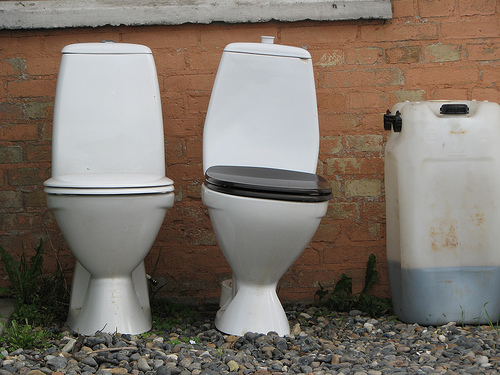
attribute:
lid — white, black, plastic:
[35, 161, 158, 201]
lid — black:
[193, 145, 335, 211]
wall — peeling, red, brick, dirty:
[319, 38, 454, 158]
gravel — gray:
[167, 331, 229, 371]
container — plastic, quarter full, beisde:
[368, 78, 484, 247]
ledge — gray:
[132, 7, 220, 29]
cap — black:
[425, 96, 473, 114]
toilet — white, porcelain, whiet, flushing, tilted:
[190, 28, 317, 214]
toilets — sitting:
[44, 38, 379, 323]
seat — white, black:
[212, 152, 350, 240]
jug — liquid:
[384, 210, 476, 314]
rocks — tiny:
[326, 310, 396, 365]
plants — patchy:
[23, 246, 59, 285]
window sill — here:
[69, 2, 211, 38]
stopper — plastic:
[368, 68, 475, 144]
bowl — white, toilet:
[197, 176, 294, 267]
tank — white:
[45, 40, 181, 136]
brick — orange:
[336, 126, 388, 199]